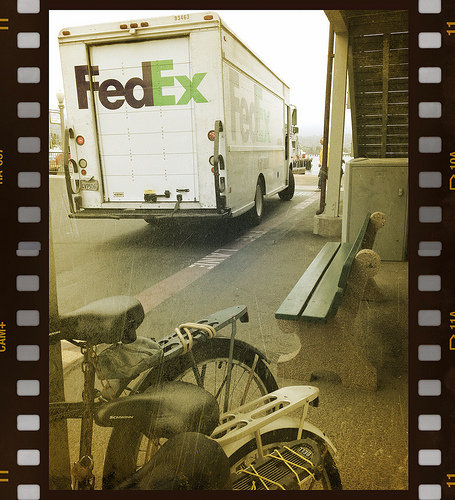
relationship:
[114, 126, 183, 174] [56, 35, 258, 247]
white on truck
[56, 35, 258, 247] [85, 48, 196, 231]
truck closed door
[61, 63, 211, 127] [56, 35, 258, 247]
logo on truck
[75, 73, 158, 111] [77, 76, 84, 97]
letters in black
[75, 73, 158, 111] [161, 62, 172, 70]
letters in green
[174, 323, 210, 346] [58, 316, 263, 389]
locks on bike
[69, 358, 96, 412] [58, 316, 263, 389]
chain on bike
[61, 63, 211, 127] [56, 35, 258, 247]
fedex on truck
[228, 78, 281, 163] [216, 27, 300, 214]
logo on side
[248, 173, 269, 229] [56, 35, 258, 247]
tire on truck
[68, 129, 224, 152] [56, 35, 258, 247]
light on truck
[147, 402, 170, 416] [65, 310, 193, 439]
black on seats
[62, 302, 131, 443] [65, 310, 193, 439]
two black seats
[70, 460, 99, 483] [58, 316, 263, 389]
lock on bike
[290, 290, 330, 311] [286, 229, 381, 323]
wood on bench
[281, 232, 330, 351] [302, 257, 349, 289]
vacant bench seat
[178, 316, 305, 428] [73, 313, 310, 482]
racks behind bikes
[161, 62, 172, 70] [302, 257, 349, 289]
green on seat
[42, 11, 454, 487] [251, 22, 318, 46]
photo taken day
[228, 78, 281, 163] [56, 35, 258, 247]
fedex side truck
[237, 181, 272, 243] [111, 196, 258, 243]
tire on rear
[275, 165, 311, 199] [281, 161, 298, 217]
tire on right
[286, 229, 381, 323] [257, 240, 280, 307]
bench on sidewalk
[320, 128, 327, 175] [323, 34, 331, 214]
man behind pole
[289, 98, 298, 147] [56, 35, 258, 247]
mirror on truck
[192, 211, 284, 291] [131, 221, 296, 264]
firelane written curb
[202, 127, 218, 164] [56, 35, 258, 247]
signal on truck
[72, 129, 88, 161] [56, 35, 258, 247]
left signal on truck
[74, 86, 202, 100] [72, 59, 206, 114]
multicolor on logo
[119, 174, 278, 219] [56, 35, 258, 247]
back wheel on truck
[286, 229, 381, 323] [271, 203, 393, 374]
bench sitting public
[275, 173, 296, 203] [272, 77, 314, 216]
tire on front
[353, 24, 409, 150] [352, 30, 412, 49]
back of stairs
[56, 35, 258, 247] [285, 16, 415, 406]
truck leaving building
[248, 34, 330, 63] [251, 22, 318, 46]
clouds in sky